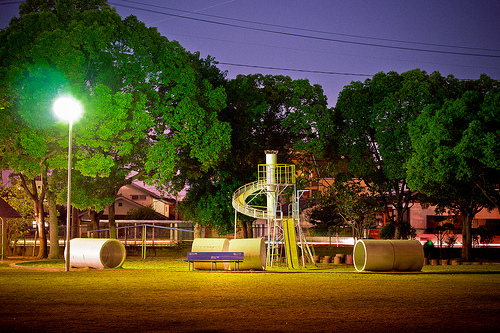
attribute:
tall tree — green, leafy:
[0, 1, 151, 255]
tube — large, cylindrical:
[48, 228, 121, 270]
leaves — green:
[407, 94, 499, 212]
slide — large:
[229, 149, 321, 273]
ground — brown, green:
[1, 251, 498, 329]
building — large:
[329, 171, 499, 246]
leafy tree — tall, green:
[1, 0, 233, 262]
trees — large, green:
[111, 45, 236, 159]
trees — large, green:
[230, 72, 346, 147]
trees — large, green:
[323, 72, 485, 202]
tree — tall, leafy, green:
[333, 69, 498, 264]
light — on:
[49, 92, 112, 137]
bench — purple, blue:
[181, 244, 249, 272]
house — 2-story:
[81, 179, 193, 249]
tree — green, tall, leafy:
[219, 74, 334, 169]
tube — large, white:
[350, 236, 427, 279]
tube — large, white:
[190, 233, 263, 270]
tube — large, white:
[64, 233, 129, 271]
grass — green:
[3, 252, 494, 332]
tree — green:
[404, 76, 499, 258]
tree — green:
[332, 66, 467, 240]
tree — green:
[181, 74, 334, 226]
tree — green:
[5, 0, 152, 266]